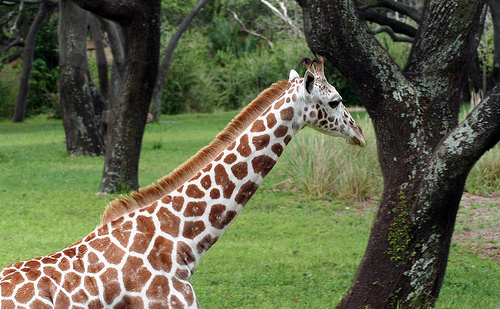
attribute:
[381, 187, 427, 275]
moss — green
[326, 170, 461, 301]
trunk — tree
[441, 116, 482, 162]
bark — grey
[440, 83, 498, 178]
branch — tree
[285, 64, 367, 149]
head — mostly white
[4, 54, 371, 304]
giraffe — brown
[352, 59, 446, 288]
moss — green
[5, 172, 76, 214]
grass — green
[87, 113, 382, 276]
giraffe — spotted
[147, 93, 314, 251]
neck — long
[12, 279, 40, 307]
spot — brown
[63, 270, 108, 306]
spot — brown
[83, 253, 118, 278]
spot — brown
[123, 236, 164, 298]
spot — brown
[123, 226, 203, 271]
spot — brown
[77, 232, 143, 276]
spot — brown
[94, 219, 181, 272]
spot — brown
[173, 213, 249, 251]
spot — brown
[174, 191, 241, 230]
spot — brown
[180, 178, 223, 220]
spot — brown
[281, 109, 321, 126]
spot — brown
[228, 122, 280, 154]
spot — brown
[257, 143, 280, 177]
spot — brown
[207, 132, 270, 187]
spot — brown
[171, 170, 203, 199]
spot — brown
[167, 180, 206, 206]
spot — brown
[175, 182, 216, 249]
spot — brown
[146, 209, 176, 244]
spot — brown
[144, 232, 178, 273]
spot — brown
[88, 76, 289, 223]
mane — red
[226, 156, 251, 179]
giraffe — brown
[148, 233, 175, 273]
spot — brown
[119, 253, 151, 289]
spot — brown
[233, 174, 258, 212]
spot — brown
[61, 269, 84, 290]
spot — brown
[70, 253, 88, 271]
spot — brown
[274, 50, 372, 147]
head —  giraffe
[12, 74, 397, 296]
green grass — green 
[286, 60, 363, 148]
head — white